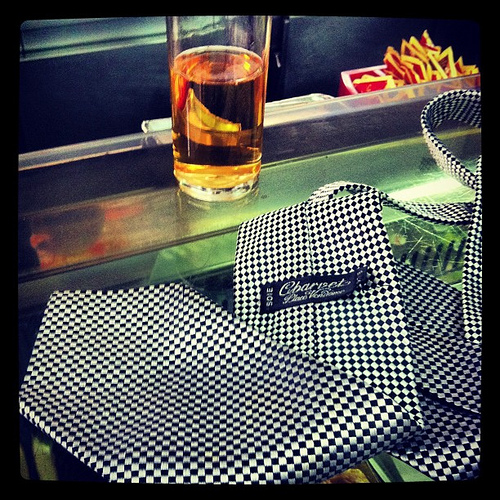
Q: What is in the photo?
A: A tie.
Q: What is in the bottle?
A: A drink.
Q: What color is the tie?
A: Black and white.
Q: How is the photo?
A: Clear.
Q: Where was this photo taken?
A: At a restaurant.